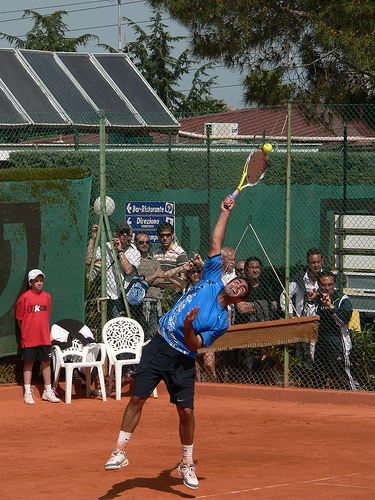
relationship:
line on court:
[255, 460, 362, 493] [67, 388, 371, 479]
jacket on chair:
[48, 318, 102, 384] [48, 317, 109, 405]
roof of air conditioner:
[15, 99, 373, 149] [202, 121, 240, 146]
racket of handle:
[224, 148, 269, 209] [228, 183, 243, 198]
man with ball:
[129, 212, 283, 413] [226, 111, 303, 174]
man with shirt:
[104, 194, 252, 490] [152, 252, 232, 357]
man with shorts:
[104, 194, 252, 490] [129, 328, 198, 408]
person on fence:
[133, 230, 161, 324] [2, 114, 371, 390]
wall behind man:
[7, 171, 365, 389] [104, 194, 252, 490]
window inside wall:
[324, 210, 373, 303] [6, 148, 373, 285]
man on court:
[104, 194, 252, 490] [1, 356, 358, 491]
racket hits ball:
[224, 148, 269, 209] [262, 141, 273, 153]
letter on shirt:
[17, 294, 46, 320] [10, 286, 68, 353]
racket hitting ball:
[225, 144, 270, 206] [261, 143, 272, 153]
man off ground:
[99, 195, 247, 485] [220, 394, 361, 497]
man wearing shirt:
[104, 194, 252, 490] [168, 251, 227, 353]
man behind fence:
[227, 238, 296, 311] [193, 134, 373, 397]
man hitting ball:
[104, 194, 252, 490] [261, 140, 274, 152]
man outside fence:
[104, 194, 252, 490] [130, 227, 295, 307]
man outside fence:
[155, 226, 181, 302] [2, 114, 371, 390]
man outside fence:
[133, 232, 165, 331] [2, 114, 371, 390]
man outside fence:
[85, 216, 139, 317] [2, 114, 371, 390]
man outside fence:
[309, 270, 349, 384] [2, 114, 371, 390]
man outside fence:
[234, 256, 278, 325] [2, 114, 371, 390]